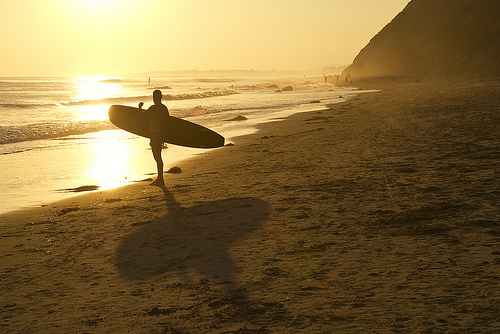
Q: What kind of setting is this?
A: Beach.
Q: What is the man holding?
A: Surfboard.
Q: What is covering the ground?
A: Sand.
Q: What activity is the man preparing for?
A: Surfing.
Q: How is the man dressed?
A: Swimsuit.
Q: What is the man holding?
A: Surfboard.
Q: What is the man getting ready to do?
A: Surf.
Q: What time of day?
A: Sunset.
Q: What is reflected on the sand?
A: Man's shadow.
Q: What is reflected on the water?
A: Sun.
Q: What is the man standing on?
A: Sand.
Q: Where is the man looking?
A: At the ocean.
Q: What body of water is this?
A: Ocean.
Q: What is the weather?
A: Sunny.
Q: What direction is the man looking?
A: Left.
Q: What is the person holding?
A: Surfboard.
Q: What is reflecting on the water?
A: Sunlight.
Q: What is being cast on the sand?
A: Shadow.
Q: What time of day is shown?
A: Sunset.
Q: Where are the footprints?
A: In the sand.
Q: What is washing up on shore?
A: Water.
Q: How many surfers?
A: One.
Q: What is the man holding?
A: Surfboard.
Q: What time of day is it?
A: Late evening.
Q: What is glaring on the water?
A: The sun.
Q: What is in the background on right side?
A: Hill.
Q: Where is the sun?
A: In the sky.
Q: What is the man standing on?
A: Sand.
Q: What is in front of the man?
A: Water.